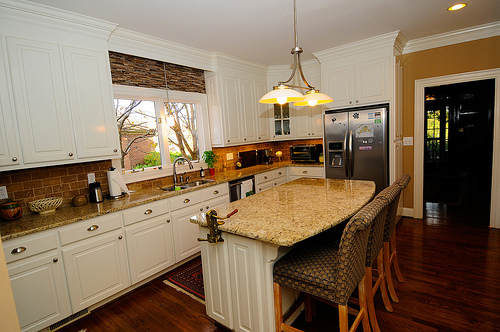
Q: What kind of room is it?
A: It is a kitchen.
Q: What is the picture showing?
A: It is showing a kitchen.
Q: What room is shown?
A: It is a kitchen.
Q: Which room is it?
A: It is a kitchen.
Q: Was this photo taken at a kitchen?
A: Yes, it was taken in a kitchen.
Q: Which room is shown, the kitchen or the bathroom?
A: It is the kitchen.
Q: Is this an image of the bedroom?
A: No, the picture is showing the kitchen.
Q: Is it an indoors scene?
A: Yes, it is indoors.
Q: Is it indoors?
A: Yes, it is indoors.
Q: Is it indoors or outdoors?
A: It is indoors.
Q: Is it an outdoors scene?
A: No, it is indoors.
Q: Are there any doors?
A: Yes, there is a door.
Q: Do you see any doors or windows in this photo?
A: Yes, there is a door.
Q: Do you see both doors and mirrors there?
A: No, there is a door but no mirrors.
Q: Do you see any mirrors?
A: No, there are no mirrors.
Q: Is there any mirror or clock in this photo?
A: No, there are no mirrors or clocks.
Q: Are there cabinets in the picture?
A: Yes, there is a cabinet.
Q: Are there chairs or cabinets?
A: Yes, there is a cabinet.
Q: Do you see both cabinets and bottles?
A: No, there is a cabinet but no bottles.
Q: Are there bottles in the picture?
A: No, there are no bottles.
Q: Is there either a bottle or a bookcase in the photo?
A: No, there are no bottles or bookcases.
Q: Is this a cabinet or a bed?
A: This is a cabinet.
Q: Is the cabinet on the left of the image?
A: Yes, the cabinet is on the left of the image.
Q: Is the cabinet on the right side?
A: No, the cabinet is on the left of the image.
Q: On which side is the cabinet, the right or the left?
A: The cabinet is on the left of the image.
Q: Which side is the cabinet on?
A: The cabinet is on the left of the image.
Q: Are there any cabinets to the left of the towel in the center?
A: Yes, there is a cabinet to the left of the towel.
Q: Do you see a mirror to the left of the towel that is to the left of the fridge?
A: No, there is a cabinet to the left of the towel.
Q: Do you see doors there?
A: Yes, there is a door.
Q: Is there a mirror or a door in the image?
A: Yes, there is a door.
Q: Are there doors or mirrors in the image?
A: Yes, there is a door.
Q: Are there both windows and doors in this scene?
A: Yes, there are both a door and windows.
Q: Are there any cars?
A: No, there are no cars.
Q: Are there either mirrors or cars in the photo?
A: No, there are no cars or mirrors.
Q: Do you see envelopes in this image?
A: No, there are no envelopes.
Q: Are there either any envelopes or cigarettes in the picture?
A: No, there are no envelopes or cigarettes.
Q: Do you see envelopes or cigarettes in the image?
A: No, there are no envelopes or cigarettes.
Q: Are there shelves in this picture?
A: No, there are no shelves.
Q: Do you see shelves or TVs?
A: No, there are no shelves or tvs.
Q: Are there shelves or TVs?
A: No, there are no shelves or tvs.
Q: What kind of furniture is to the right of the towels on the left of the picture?
A: The pieces of furniture are drawers.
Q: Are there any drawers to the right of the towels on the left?
A: Yes, there are drawers to the right of the towels.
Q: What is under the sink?
A: The drawers are under the sink.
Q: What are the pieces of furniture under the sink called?
A: The pieces of furniture are drawers.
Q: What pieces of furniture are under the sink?
A: The pieces of furniture are drawers.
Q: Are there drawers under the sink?
A: Yes, there are drawers under the sink.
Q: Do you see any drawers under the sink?
A: Yes, there are drawers under the sink.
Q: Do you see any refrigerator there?
A: Yes, there is a refrigerator.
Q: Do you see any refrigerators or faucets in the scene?
A: Yes, there is a refrigerator.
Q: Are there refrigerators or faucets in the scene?
A: Yes, there is a refrigerator.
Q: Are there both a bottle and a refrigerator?
A: No, there is a refrigerator but no bottles.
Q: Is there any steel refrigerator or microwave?
A: Yes, there is a steel refrigerator.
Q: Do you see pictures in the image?
A: No, there are no pictures.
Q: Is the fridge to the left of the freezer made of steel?
A: Yes, the fridge is made of steel.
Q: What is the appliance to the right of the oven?
A: The appliance is a refrigerator.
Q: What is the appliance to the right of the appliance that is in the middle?
A: The appliance is a refrigerator.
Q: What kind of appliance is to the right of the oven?
A: The appliance is a refrigerator.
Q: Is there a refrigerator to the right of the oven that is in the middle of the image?
A: Yes, there is a refrigerator to the right of the oven.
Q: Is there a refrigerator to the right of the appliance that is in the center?
A: Yes, there is a refrigerator to the right of the oven.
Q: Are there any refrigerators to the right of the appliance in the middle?
A: Yes, there is a refrigerator to the right of the oven.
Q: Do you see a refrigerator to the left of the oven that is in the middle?
A: No, the refrigerator is to the right of the oven.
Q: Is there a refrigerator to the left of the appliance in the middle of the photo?
A: No, the refrigerator is to the right of the oven.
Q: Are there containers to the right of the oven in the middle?
A: No, there is a refrigerator to the right of the oven.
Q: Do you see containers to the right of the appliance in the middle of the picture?
A: No, there is a refrigerator to the right of the oven.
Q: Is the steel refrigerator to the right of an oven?
A: Yes, the refrigerator is to the right of an oven.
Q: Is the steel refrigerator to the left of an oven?
A: No, the fridge is to the right of an oven.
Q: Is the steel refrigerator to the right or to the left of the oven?
A: The fridge is to the right of the oven.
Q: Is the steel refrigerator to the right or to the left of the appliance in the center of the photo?
A: The fridge is to the right of the oven.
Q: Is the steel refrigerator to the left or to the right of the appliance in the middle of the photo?
A: The fridge is to the right of the oven.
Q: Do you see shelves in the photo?
A: No, there are no shelves.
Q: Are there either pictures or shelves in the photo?
A: No, there are no shelves or pictures.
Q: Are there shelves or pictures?
A: No, there are no shelves or pictures.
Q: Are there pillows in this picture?
A: No, there are no pillows.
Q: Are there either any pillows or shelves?
A: No, there are no pillows or shelves.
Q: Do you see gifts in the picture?
A: No, there are no gifts.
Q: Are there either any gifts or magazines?
A: No, there are no gifts or magazines.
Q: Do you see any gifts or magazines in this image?
A: No, there are no gifts or magazines.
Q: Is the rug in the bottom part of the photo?
A: Yes, the rug is in the bottom of the image.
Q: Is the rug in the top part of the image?
A: No, the rug is in the bottom of the image.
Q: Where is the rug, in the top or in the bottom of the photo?
A: The rug is in the bottom of the image.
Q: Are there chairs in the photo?
A: Yes, there is a chair.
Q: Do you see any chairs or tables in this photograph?
A: Yes, there is a chair.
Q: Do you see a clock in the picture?
A: No, there are no clocks.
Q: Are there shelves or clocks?
A: No, there are no clocks or shelves.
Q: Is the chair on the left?
A: No, the chair is on the right of the image.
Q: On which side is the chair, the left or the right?
A: The chair is on the right of the image.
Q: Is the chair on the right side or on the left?
A: The chair is on the right of the image.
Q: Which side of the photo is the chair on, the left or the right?
A: The chair is on the right of the image.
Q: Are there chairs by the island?
A: Yes, there is a chair by the island.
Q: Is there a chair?
A: Yes, there is a chair.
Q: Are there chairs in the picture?
A: Yes, there is a chair.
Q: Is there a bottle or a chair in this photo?
A: Yes, there is a chair.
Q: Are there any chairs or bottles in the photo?
A: Yes, there is a chair.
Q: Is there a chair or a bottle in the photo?
A: Yes, there is a chair.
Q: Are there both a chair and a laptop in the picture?
A: No, there is a chair but no laptops.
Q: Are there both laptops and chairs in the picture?
A: No, there is a chair but no laptops.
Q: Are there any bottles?
A: No, there are no bottles.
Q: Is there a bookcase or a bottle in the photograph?
A: No, there are no bottles or bookcases.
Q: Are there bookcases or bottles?
A: No, there are no bottles or bookcases.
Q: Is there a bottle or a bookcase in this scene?
A: No, there are no bottles or bookcases.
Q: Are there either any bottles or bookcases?
A: No, there are no bottles or bookcases.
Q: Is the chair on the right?
A: Yes, the chair is on the right of the image.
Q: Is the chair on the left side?
A: No, the chair is on the right of the image.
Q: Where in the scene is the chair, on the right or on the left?
A: The chair is on the right of the image.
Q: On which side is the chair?
A: The chair is on the right of the image.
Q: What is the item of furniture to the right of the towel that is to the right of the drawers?
A: The piece of furniture is a chair.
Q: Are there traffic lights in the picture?
A: No, there are no traffic lights.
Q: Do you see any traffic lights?
A: No, there are no traffic lights.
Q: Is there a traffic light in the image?
A: No, there are no traffic lights.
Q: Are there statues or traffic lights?
A: No, there are no traffic lights or statues.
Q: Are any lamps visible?
A: Yes, there is a lamp.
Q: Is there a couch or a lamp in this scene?
A: Yes, there is a lamp.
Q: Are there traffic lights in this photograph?
A: No, there are no traffic lights.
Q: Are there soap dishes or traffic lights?
A: No, there are no traffic lights or soap dishes.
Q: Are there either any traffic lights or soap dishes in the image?
A: No, there are no traffic lights or soap dishes.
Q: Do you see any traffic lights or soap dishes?
A: No, there are no traffic lights or soap dishes.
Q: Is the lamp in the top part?
A: Yes, the lamp is in the top of the image.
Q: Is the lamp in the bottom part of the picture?
A: No, the lamp is in the top of the image.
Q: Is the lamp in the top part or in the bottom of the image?
A: The lamp is in the top of the image.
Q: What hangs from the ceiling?
A: The lamp hangs from the ceiling.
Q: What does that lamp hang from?
A: The lamp hangs from the ceiling.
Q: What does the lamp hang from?
A: The lamp hangs from the ceiling.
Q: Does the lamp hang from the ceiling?
A: Yes, the lamp hangs from the ceiling.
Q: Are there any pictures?
A: No, there are no pictures.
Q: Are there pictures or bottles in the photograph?
A: No, there are no pictures or bottles.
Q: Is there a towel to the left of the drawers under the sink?
A: Yes, there are towels to the left of the drawers.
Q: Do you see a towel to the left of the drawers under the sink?
A: Yes, there are towels to the left of the drawers.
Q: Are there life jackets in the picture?
A: No, there are no life jackets.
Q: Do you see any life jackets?
A: No, there are no life jackets.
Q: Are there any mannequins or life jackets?
A: No, there are no life jackets or mannequins.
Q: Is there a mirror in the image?
A: No, there are no mirrors.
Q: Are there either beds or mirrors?
A: No, there are no mirrors or beds.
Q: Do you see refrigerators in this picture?
A: Yes, there is a refrigerator.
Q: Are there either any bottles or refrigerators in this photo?
A: Yes, there is a refrigerator.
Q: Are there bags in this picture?
A: No, there are no bags.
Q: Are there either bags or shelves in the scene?
A: No, there are no bags or shelves.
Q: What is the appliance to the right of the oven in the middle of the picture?
A: The appliance is a refrigerator.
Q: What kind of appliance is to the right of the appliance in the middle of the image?
A: The appliance is a refrigerator.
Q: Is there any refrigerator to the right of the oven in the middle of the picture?
A: Yes, there is a refrigerator to the right of the oven.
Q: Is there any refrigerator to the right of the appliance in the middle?
A: Yes, there is a refrigerator to the right of the oven.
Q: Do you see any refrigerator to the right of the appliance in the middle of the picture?
A: Yes, there is a refrigerator to the right of the oven.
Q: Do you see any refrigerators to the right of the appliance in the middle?
A: Yes, there is a refrigerator to the right of the oven.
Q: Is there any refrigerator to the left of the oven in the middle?
A: No, the refrigerator is to the right of the oven.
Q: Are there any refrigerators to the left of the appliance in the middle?
A: No, the refrigerator is to the right of the oven.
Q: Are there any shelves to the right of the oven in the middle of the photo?
A: No, there is a refrigerator to the right of the oven.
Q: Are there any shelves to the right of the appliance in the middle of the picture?
A: No, there is a refrigerator to the right of the oven.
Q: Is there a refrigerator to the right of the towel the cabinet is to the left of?
A: Yes, there is a refrigerator to the right of the towel.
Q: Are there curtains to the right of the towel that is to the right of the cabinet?
A: No, there is a refrigerator to the right of the towel.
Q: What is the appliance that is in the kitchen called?
A: The appliance is a refrigerator.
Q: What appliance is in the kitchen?
A: The appliance is a refrigerator.